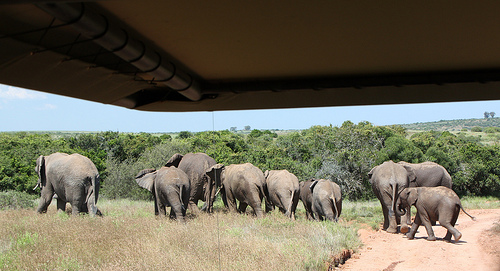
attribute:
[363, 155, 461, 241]
elephant — large, grey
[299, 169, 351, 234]
elephant — grey, large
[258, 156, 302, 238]
elephant — large, grey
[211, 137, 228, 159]
leaf — green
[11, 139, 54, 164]
leaf — green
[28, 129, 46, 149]
leaf — green